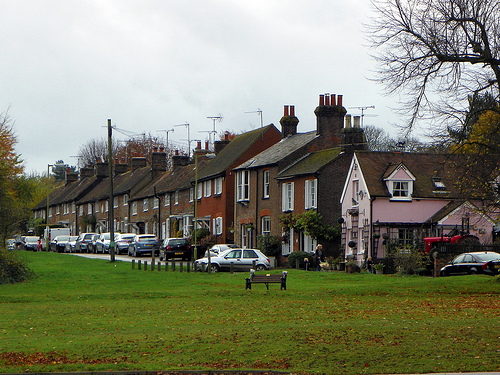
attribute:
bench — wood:
[241, 266, 290, 296]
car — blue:
[161, 235, 188, 260]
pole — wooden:
[104, 117, 119, 263]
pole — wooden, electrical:
[79, 105, 126, 265]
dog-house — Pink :
[380, 159, 417, 204]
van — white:
[41, 227, 71, 247]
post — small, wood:
[130, 256, 205, 273]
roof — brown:
[355, 148, 499, 200]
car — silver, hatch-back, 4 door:
[199, 245, 277, 278]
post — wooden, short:
[131, 258, 201, 278]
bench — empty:
[244, 270, 288, 292]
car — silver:
[193, 245, 271, 272]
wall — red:
[199, 203, 221, 212]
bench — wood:
[235, 270, 297, 292]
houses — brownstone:
[30, 133, 397, 233]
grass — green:
[7, 286, 499, 370]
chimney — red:
[274, 80, 366, 148]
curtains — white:
[393, 183, 409, 192]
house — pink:
[336, 140, 484, 264]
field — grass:
[35, 284, 208, 351]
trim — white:
[316, 143, 449, 329]